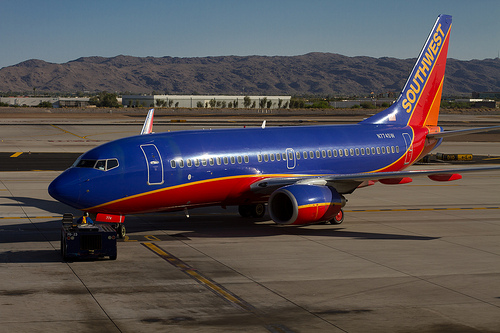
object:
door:
[140, 144, 165, 186]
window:
[393, 147, 395, 152]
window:
[362, 149, 365, 154]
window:
[329, 151, 331, 156]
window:
[304, 152, 307, 158]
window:
[170, 157, 177, 169]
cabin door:
[139, 142, 164, 186]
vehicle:
[60, 212, 117, 261]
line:
[188, 278, 239, 303]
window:
[196, 159, 199, 165]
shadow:
[0, 225, 59, 242]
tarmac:
[0, 125, 73, 151]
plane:
[46, 13, 498, 227]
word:
[401, 20, 444, 112]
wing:
[250, 164, 500, 194]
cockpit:
[75, 157, 120, 172]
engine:
[268, 181, 348, 225]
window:
[93, 157, 108, 170]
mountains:
[0, 49, 104, 94]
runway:
[0, 259, 499, 333]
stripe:
[166, 170, 248, 195]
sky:
[0, 0, 145, 49]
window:
[105, 154, 119, 169]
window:
[72, 157, 95, 168]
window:
[180, 160, 183, 166]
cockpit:
[71, 157, 121, 171]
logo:
[400, 23, 446, 113]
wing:
[140, 108, 156, 135]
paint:
[111, 142, 138, 157]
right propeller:
[267, 178, 348, 225]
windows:
[209, 158, 212, 165]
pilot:
[164, 158, 171, 167]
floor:
[156, 126, 203, 133]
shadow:
[204, 225, 261, 237]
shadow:
[36, 199, 57, 209]